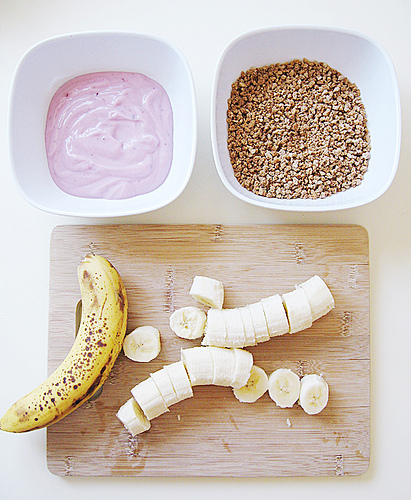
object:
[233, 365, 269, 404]
sliced banana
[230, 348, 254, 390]
sliced banana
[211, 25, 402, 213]
bowl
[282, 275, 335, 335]
slice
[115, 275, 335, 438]
banana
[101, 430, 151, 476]
banana juice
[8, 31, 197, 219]
bowl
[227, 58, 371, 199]
granola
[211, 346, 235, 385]
slice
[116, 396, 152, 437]
slice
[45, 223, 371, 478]
board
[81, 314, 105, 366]
spot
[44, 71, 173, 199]
pink yogurt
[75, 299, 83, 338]
handle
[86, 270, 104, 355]
banana peel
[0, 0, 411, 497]
counter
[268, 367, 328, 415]
banana slice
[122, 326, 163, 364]
banana slice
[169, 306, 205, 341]
banana slice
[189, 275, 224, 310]
banana slice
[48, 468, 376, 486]
edge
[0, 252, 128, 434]
banana